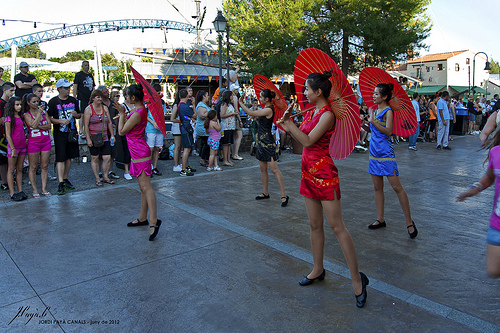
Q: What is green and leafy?
A: Tree.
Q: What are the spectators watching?
A: The performance.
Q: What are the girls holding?
A: Umbrellas.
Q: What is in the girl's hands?
A: Umbrellas.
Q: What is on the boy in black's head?
A: White cap.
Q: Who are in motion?
A: The performers.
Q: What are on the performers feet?
A: Black shoes.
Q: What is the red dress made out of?
A: Silk.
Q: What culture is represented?
A: Eastern.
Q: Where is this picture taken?
A: A dance performance.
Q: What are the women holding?
A: Umbrellas.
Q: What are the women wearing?
A: Dresses.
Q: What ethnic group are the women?
A: Asian.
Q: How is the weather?
A: Clear.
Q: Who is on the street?
A: People.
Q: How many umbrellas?
A: 4.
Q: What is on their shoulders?
A: Umbrella.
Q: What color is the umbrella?
A: Red.